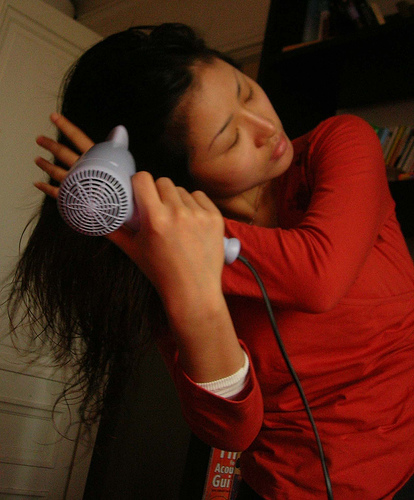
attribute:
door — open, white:
[0, 314, 52, 464]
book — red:
[175, 429, 241, 497]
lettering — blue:
[212, 462, 231, 486]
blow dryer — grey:
[54, 126, 136, 232]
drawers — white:
[1, 375, 71, 482]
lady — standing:
[0, 17, 412, 497]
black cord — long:
[227, 250, 353, 498]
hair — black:
[17, 44, 250, 410]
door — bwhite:
[8, 24, 67, 429]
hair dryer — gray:
[34, 132, 233, 268]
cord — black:
[234, 252, 344, 498]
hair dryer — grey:
[54, 136, 240, 264]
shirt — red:
[157, 113, 410, 497]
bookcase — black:
[100, 422, 182, 475]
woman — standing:
[30, 18, 409, 494]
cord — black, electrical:
[235, 255, 334, 498]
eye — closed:
[243, 78, 252, 105]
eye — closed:
[224, 127, 240, 150]